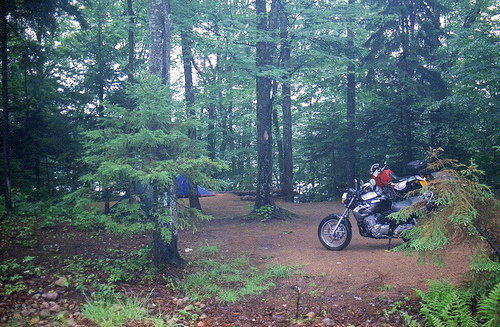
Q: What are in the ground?
A: Bike.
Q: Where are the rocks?
A: On the ground.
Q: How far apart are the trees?
A: Several feet.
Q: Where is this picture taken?
A: Campsite.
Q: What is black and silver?
A: Motorcycle.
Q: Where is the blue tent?
A: Among the trees.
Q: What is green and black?
A: Trees.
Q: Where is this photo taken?
A: Forest clearing.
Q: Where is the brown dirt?
A: On the ground.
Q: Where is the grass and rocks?
A: Around the tree.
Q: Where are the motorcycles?
A: Parked on trail.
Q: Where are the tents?
A: Behind the trees.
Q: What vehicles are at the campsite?
A: Motorcycles.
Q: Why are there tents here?
A: It is a campsite.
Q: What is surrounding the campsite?
A: Trees.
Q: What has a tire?
A: The motorcycle.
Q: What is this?
A: A forest clearing.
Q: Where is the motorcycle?
A: Inside the clearing.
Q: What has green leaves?
A: The trees.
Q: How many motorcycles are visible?
A: One.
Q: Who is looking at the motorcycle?
A: The photographer.